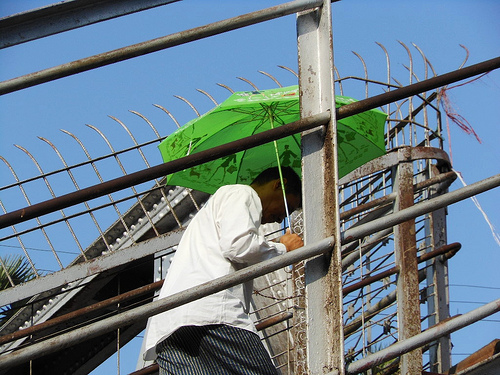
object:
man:
[140, 164, 301, 375]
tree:
[340, 339, 400, 374]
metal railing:
[0, 0, 499, 374]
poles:
[332, 75, 457, 233]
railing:
[2, 1, 498, 372]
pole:
[0, 56, 500, 229]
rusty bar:
[0, 112, 317, 234]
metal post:
[394, 146, 422, 373]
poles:
[339, 146, 448, 375]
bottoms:
[154, 324, 279, 374]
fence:
[1, 40, 470, 373]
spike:
[396, 39, 410, 54]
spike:
[277, 65, 297, 76]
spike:
[215, 83, 228, 90]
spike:
[152, 103, 169, 115]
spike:
[37, 136, 56, 149]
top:
[1, 39, 473, 194]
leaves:
[0, 255, 37, 291]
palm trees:
[1, 255, 51, 320]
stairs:
[0, 176, 211, 375]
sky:
[131, 59, 204, 92]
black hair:
[249, 166, 302, 195]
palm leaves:
[2, 252, 40, 284]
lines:
[448, 284, 490, 288]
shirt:
[142, 183, 288, 361]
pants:
[152, 324, 280, 374]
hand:
[280, 227, 303, 250]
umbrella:
[156, 84, 388, 195]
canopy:
[156, 84, 388, 193]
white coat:
[140, 184, 287, 360]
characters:
[279, 145, 298, 167]